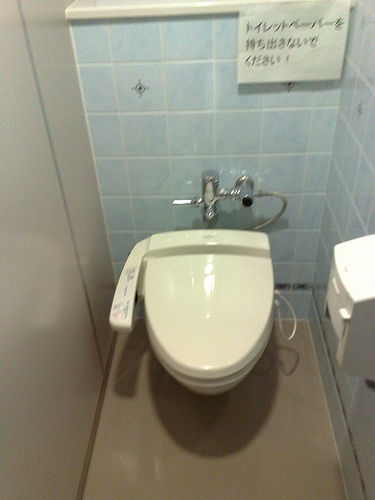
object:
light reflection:
[203, 257, 217, 300]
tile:
[173, 107, 315, 151]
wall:
[86, 43, 369, 190]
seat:
[138, 247, 275, 395]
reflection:
[10, 242, 72, 327]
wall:
[1, 195, 92, 457]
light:
[203, 263, 215, 297]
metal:
[166, 163, 287, 231]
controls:
[110, 242, 156, 337]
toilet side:
[96, 228, 303, 399]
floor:
[79, 323, 346, 497]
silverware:
[173, 169, 288, 225]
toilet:
[108, 169, 274, 403]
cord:
[272, 289, 298, 342]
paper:
[236, 3, 353, 83]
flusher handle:
[172, 196, 205, 208]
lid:
[143, 246, 273, 381]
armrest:
[108, 249, 142, 329]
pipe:
[252, 180, 289, 237]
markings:
[109, 266, 135, 321]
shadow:
[152, 385, 273, 461]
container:
[308, 234, 375, 381]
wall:
[298, 130, 373, 427]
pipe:
[201, 164, 218, 226]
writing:
[244, 16, 345, 67]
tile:
[123, 112, 170, 159]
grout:
[96, 143, 133, 175]